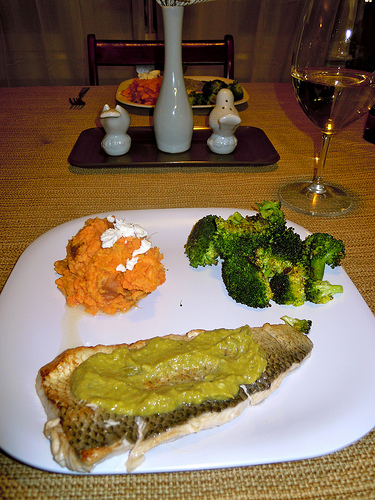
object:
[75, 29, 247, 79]
chair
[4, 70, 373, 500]
table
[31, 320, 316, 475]
fish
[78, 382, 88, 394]
mustard sauce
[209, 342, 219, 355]
sauce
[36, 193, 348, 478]
meal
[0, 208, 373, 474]
plate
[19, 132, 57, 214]
table cloth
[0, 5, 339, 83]
curtains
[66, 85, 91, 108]
fork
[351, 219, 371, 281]
tablecloth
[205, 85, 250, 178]
bird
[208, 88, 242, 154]
bird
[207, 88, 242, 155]
salt shaker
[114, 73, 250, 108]
plate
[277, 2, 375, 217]
glass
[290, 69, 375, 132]
wine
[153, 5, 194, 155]
porcelain vase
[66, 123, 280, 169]
tray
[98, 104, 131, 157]
shakers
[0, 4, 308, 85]
window